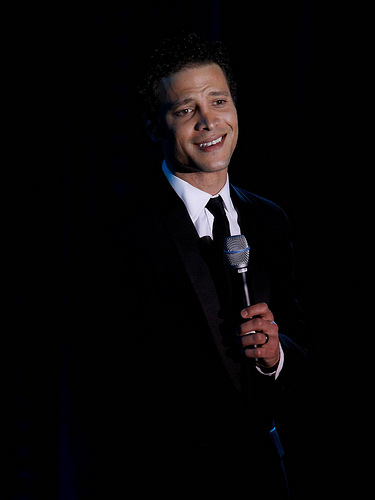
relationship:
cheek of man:
[161, 117, 193, 153] [108, 28, 325, 379]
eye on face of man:
[170, 97, 197, 121] [111, 43, 302, 500]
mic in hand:
[224, 233, 264, 360] [235, 301, 280, 369]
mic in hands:
[224, 233, 264, 360] [236, 293, 296, 365]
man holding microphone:
[111, 43, 302, 500] [223, 233, 258, 362]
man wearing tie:
[111, 43, 302, 500] [206, 195, 230, 255]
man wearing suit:
[71, 27, 370, 497] [104, 182, 292, 496]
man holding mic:
[111, 43, 302, 500] [224, 233, 264, 360]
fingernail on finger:
[239, 306, 249, 318] [237, 302, 271, 317]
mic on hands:
[224, 233, 264, 360] [238, 297, 285, 373]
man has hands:
[111, 43, 302, 500] [238, 297, 285, 373]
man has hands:
[111, 43, 302, 500] [231, 302, 285, 371]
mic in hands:
[224, 233, 264, 360] [231, 302, 285, 371]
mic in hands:
[215, 230, 285, 361] [238, 303, 280, 375]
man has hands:
[111, 43, 302, 500] [238, 303, 280, 375]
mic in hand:
[224, 233, 264, 360] [241, 298, 282, 369]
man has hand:
[111, 43, 302, 500] [241, 298, 282, 369]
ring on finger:
[260, 329, 270, 347] [240, 331, 272, 343]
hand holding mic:
[224, 303, 290, 360] [224, 233, 264, 360]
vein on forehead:
[156, 82, 187, 97] [154, 62, 231, 116]